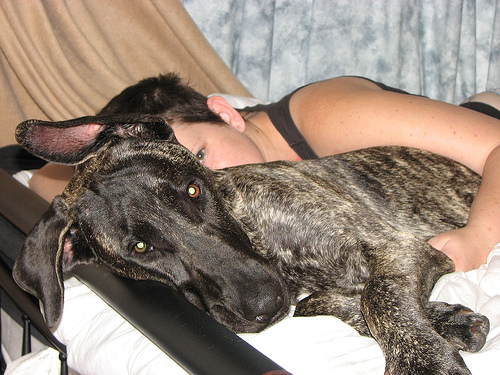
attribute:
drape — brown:
[0, 44, 66, 126]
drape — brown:
[0, 15, 77, 120]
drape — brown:
[6, 0, 91, 122]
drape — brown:
[29, 0, 112, 117]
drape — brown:
[54, 0, 138, 93]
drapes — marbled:
[287, 39, 317, 62]